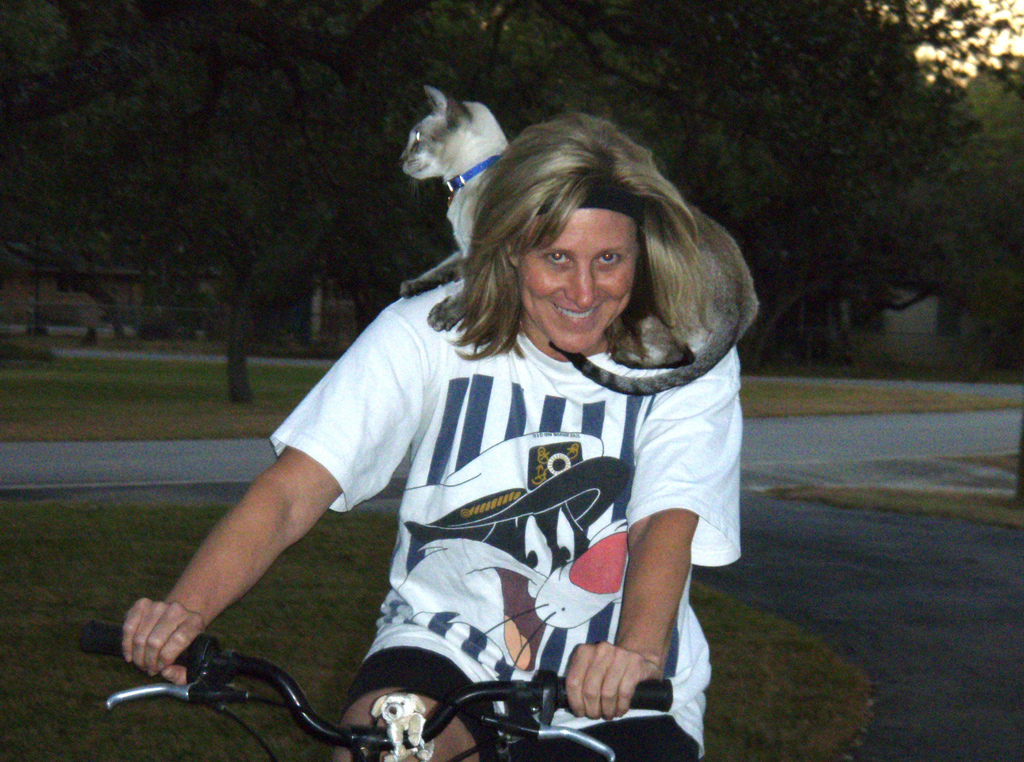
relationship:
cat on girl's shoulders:
[395, 84, 760, 393] [382, 247, 778, 435]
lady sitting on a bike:
[120, 113, 747, 761] [77, 622, 699, 758]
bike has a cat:
[77, 622, 699, 758] [395, 84, 760, 393]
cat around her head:
[395, 84, 760, 393] [464, 106, 706, 418]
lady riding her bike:
[120, 113, 747, 761] [194, 599, 575, 755]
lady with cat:
[430, 91, 748, 541] [356, 5, 558, 250]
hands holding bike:
[121, 592, 670, 703] [77, 622, 699, 758]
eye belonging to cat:
[410, 126, 426, 144] [395, 84, 760, 393]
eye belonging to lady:
[594, 247, 621, 265] [120, 113, 747, 761]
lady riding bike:
[120, 113, 747, 761] [77, 622, 699, 758]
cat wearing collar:
[395, 84, 760, 393] [441, 152, 504, 194]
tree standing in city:
[102, 3, 358, 405] [2, 1, 992, 758]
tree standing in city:
[0, 0, 1013, 406] [2, 1, 992, 758]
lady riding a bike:
[120, 113, 747, 761] [118, 619, 553, 753]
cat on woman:
[395, 84, 760, 393] [413, 106, 777, 608]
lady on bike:
[120, 113, 747, 761] [77, 622, 699, 758]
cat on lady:
[395, 84, 760, 393] [120, 113, 747, 761]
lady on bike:
[112, 109, 774, 732] [106, 517, 703, 744]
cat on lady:
[380, 50, 767, 396] [112, 109, 774, 732]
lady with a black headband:
[120, 113, 747, 761] [537, 173, 658, 217]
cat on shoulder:
[395, 84, 760, 393] [384, 279, 758, 401]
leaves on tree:
[819, 50, 880, 109] [69, 13, 906, 476]